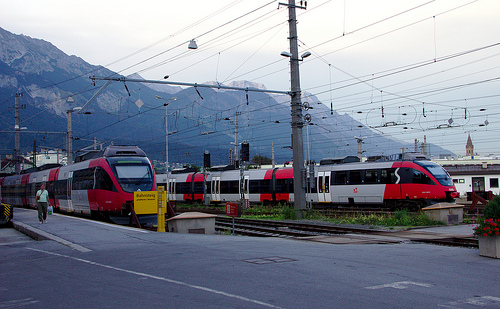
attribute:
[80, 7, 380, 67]
clouds — white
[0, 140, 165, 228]
train — grey and red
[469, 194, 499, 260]
bush — rose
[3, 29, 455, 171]
mountains — rocky, beautiful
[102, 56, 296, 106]
rod — metal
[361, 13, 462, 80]
clouds — white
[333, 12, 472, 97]
sky — blue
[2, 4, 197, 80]
clouds — white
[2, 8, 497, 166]
sky — blue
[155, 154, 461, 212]
red train — red and gray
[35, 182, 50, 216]
shirt — white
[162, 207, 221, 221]
brown roof — brown 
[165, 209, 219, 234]
sunken structure — Sunken 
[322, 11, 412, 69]
sky — blue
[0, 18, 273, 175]
wall — suspended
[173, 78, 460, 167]
wall — suspended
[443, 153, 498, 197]
building — white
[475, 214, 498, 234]
flowers — red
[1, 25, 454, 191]
mountains — ridge , tall